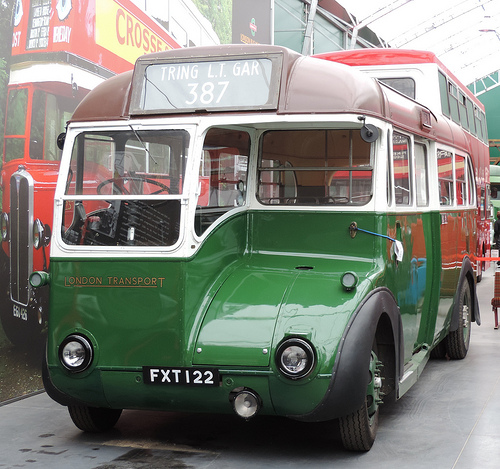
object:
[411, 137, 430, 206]
window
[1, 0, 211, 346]
bus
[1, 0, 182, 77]
billboard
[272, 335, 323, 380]
head light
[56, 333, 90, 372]
head light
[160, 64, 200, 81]
tring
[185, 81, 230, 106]
387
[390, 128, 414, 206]
window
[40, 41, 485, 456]
bus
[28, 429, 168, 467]
spots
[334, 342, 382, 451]
tire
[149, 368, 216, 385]
letters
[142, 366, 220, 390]
license plate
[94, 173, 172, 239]
steering wheel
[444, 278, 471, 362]
tire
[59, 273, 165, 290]
london transport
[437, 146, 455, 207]
window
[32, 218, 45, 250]
mirror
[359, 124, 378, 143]
mirror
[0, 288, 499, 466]
ground